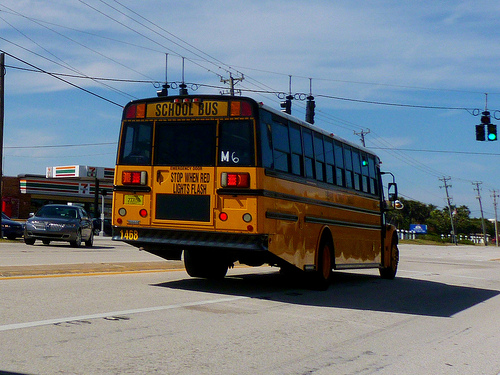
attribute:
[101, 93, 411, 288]
bus — white, yellow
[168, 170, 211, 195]
writing — black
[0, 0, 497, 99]
clouds — white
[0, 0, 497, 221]
sky — blue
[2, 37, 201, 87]
clouds — white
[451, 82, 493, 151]
traffic signal — green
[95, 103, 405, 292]
bus — yellow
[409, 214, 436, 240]
sign — blue, white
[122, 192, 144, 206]
license plate — yellow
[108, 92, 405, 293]
school bus — yellow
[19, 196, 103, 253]
car — grey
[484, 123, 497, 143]
light — green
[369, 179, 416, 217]
mirror — black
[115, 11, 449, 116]
clouds — white